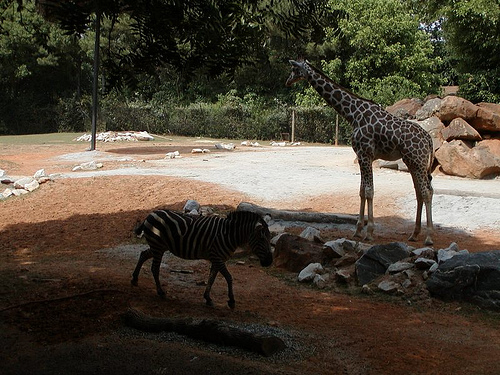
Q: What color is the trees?
A: Green.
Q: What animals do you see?
A: A zebra.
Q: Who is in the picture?
A: No one.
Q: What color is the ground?
A: Brown.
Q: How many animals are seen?
A: Two.